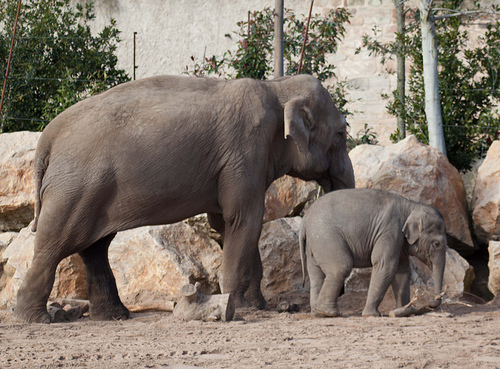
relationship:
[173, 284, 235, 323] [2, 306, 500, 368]
log on ground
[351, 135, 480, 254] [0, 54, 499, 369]
rock in enclosure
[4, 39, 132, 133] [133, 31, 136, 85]
wires on pole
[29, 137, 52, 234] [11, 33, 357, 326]
tail of elephant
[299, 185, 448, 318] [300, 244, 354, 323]
elephant has legs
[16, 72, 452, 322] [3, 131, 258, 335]
elephants near boulders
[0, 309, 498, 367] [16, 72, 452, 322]
dirt under elephants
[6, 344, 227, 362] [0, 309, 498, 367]
marks in dirt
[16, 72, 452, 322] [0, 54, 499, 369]
elephants in enclosure